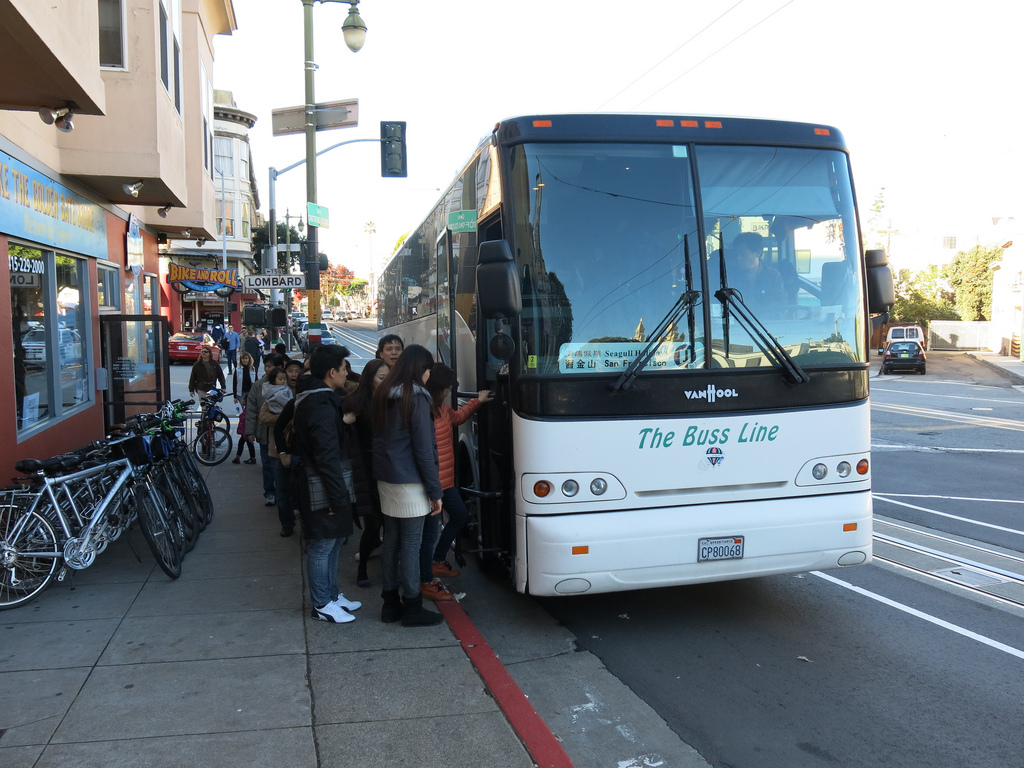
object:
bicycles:
[3, 456, 185, 605]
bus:
[365, 96, 872, 596]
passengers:
[356, 340, 439, 642]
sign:
[303, 201, 333, 229]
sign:
[170, 265, 235, 285]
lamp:
[328, 1, 384, 54]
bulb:
[340, 31, 369, 55]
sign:
[556, 336, 705, 373]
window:
[559, 145, 813, 318]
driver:
[727, 234, 770, 278]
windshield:
[498, 154, 915, 315]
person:
[287, 327, 342, 567]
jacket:
[274, 372, 342, 543]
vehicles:
[879, 320, 940, 379]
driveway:
[922, 346, 954, 377]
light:
[241, 4, 391, 286]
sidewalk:
[310, 634, 504, 736]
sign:
[17, 191, 112, 252]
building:
[8, 113, 177, 415]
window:
[47, 269, 87, 408]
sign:
[243, 273, 308, 291]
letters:
[295, 276, 303, 285]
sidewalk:
[232, 461, 260, 587]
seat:
[674, 243, 710, 313]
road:
[734, 644, 953, 753]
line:
[474, 677, 524, 723]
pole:
[273, 7, 369, 344]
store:
[11, 4, 239, 569]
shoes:
[307, 600, 350, 626]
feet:
[310, 605, 357, 627]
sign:
[273, 96, 359, 141]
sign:
[375, 122, 412, 181]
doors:
[466, 281, 524, 580]